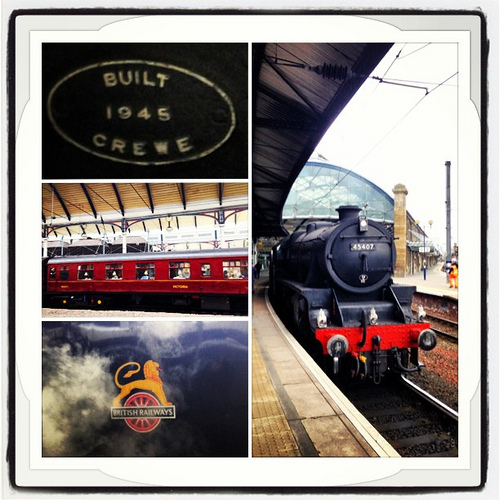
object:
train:
[269, 205, 437, 383]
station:
[251, 77, 462, 458]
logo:
[359, 274, 368, 283]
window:
[136, 263, 156, 281]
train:
[48, 247, 249, 314]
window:
[169, 262, 190, 279]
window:
[105, 264, 123, 281]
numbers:
[353, 244, 374, 250]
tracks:
[400, 374, 458, 421]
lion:
[111, 360, 177, 433]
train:
[41, 321, 249, 458]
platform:
[251, 266, 401, 459]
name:
[112, 409, 172, 416]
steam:
[338, 172, 359, 205]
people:
[141, 270, 148, 280]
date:
[107, 107, 170, 121]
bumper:
[315, 323, 429, 354]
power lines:
[253, 50, 429, 95]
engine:
[272, 205, 431, 323]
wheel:
[94, 296, 105, 310]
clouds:
[41, 320, 248, 457]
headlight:
[361, 220, 366, 226]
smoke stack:
[335, 205, 362, 220]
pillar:
[391, 183, 408, 277]